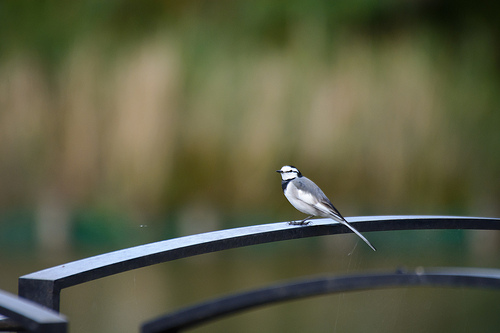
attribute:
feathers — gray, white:
[296, 185, 311, 205]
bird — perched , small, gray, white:
[268, 158, 379, 255]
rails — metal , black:
[37, 214, 281, 318]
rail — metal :
[40, 220, 267, 293]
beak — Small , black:
[273, 169, 280, 174]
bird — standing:
[271, 162, 388, 253]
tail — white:
[320, 200, 377, 255]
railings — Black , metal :
[55, 230, 291, 327]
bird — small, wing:
[275, 157, 381, 253]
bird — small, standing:
[259, 140, 388, 263]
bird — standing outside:
[259, 144, 424, 278]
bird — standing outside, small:
[246, 124, 400, 276]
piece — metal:
[0, 199, 480, 315]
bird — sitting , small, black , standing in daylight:
[268, 153, 386, 260]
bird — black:
[261, 144, 377, 258]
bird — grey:
[253, 150, 389, 259]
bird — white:
[262, 151, 385, 267]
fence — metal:
[43, 224, 213, 274]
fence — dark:
[177, 207, 262, 259]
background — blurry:
[95, 67, 211, 145]